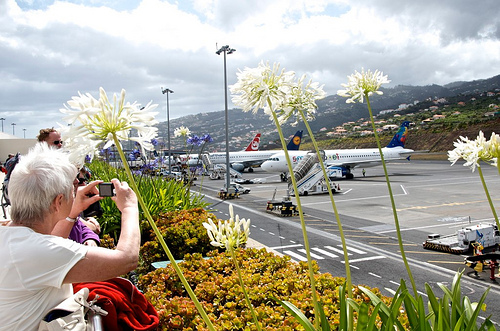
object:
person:
[1, 140, 142, 330]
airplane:
[262, 123, 414, 184]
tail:
[389, 123, 413, 148]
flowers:
[335, 68, 389, 103]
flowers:
[270, 77, 326, 126]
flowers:
[227, 60, 292, 113]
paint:
[438, 214, 469, 224]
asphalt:
[412, 185, 478, 216]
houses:
[382, 122, 399, 133]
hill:
[88, 72, 499, 132]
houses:
[358, 128, 375, 136]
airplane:
[158, 130, 263, 175]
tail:
[244, 131, 264, 150]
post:
[220, 55, 233, 194]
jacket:
[75, 274, 162, 327]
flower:
[197, 133, 213, 145]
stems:
[193, 143, 206, 182]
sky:
[2, 1, 496, 47]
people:
[36, 128, 64, 152]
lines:
[259, 190, 407, 205]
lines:
[398, 195, 492, 212]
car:
[226, 183, 251, 192]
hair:
[8, 144, 77, 224]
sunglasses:
[49, 139, 65, 146]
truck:
[291, 162, 344, 198]